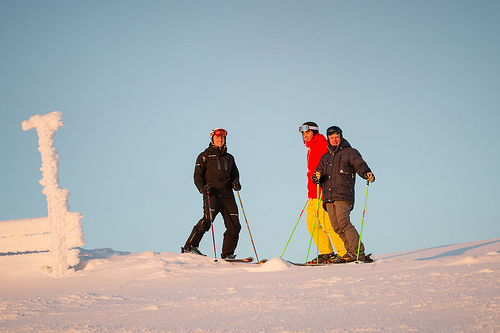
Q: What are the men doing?
A: Skiing.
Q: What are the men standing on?
A: Snow.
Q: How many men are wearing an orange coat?
A: One.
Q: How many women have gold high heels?
A: None.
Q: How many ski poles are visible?
A: Six.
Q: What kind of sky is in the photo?
A: Clear blue.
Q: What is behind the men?
A: Nothing but sky.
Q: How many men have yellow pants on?
A: One.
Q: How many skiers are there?
A: Three.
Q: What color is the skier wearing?
A: Black.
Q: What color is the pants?
A: Green with red.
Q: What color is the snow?
A: White.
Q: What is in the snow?
A: Snow formed up.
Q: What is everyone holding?
A: Ski poles.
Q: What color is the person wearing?
A: Black.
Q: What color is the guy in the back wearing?
A: Orange and red.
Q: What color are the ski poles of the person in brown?
A: Neon green.